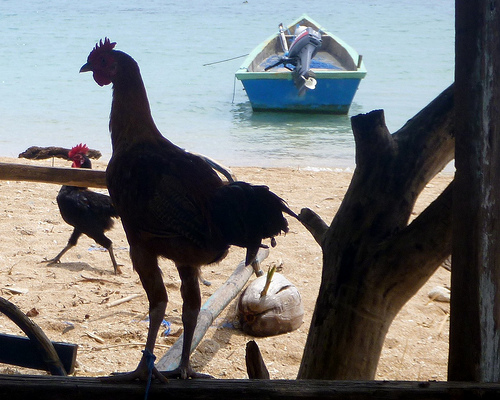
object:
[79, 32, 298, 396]
chicken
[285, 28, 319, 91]
motor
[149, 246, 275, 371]
log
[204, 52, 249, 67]
rope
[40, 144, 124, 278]
chicken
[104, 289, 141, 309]
sticks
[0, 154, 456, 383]
sand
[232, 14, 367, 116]
boat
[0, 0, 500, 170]
water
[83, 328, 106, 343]
sticks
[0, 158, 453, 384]
dirt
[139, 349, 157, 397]
string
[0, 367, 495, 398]
wood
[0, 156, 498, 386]
beach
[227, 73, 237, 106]
anchor